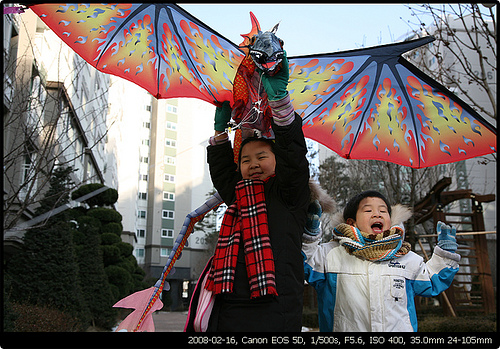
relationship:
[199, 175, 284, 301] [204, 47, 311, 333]
scarf on child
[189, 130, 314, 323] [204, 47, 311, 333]
jacket on child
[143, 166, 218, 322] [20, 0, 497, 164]
tail of kite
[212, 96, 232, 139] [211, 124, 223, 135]
glove on hand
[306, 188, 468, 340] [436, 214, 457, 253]
child wearing blue gloves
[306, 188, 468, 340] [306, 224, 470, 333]
child in a blue and white coat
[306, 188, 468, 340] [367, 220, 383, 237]
child with an open mouth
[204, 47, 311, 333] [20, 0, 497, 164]
child holding kite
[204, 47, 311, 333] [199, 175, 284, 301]
child wearing a scarf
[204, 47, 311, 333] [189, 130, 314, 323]
child wearing a black coat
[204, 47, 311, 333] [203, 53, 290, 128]
child wearing green gloves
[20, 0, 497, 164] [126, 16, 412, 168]
kite with wings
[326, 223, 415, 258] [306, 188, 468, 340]
scarf around shorter child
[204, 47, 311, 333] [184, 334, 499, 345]
child posing for a picture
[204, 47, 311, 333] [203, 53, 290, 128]
child wearing gloves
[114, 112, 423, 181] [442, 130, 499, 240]
image of downtown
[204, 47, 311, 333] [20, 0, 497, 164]
child playing with a kite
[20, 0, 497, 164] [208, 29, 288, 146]
kite looks like a dragon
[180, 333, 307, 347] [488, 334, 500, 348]
watermark on corner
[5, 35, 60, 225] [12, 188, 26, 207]
trees on left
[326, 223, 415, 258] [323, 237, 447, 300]
scarf on boy neck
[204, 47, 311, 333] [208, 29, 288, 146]
child holding dragon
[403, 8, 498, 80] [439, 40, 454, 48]
tree have no leaves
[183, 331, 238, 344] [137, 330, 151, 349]
date on bottom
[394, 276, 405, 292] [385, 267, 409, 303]
writing on pocket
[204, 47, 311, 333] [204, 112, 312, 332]
child on child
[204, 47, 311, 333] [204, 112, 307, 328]
child wearing coat